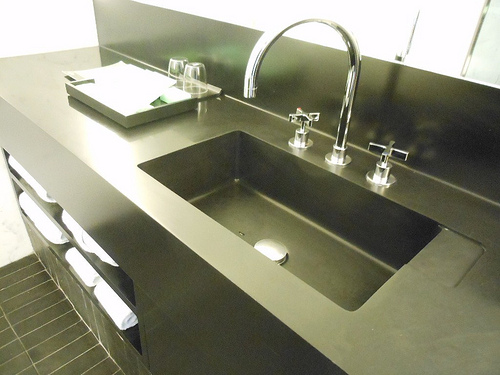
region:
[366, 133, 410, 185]
the right silver faucet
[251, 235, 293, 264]
the drain in the sink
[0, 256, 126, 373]
black floor tiles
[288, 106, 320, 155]
left silver faucet on the sink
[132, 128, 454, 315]
rectangular sink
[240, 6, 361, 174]
round spigot on the sink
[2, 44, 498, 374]
large rectangular countertop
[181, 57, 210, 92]
right clear upsidedown cup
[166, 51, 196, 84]
left clear upsidedown cup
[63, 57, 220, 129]
silver tray for accessories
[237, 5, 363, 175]
curved metal sink faucet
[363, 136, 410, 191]
silver metal sink handle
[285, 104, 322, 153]
silver metal sink handle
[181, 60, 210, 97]
clear glass cup on black counter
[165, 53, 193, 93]
clear glass cup on black counter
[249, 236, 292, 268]
silver metal drain stopper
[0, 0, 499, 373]
black sink counter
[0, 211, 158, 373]
brown tiled floor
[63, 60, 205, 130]
small rectangular tray on counter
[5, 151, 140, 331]
white folded towels on shelves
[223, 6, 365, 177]
faucet for the sink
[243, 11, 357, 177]
the faucet is silver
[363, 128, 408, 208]
handles for the sink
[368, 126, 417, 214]
the handles are silver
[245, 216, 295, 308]
drain in the sink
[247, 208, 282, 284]
the drain is silver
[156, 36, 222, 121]
cups next to the sink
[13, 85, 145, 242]
the counter is black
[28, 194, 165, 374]
towels on the shelves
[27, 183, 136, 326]
the towels are white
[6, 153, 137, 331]
Towels on a shelf.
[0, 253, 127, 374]
Tile on a floor.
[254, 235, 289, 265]
A drain in the sink.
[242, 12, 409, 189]
A faucet on a sink.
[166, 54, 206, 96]
Two upside down glasses.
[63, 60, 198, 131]
Tray and papers on a counter.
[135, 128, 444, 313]
A stainless steel sink.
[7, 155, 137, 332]
Towels under a sink.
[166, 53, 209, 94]
Two clear glasses on the counter.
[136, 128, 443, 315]
A square silver sink.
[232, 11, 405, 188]
The faucet is silver.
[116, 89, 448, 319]
The sink is rectangular.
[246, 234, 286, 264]
The drain is silver.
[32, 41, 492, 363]
The counter is black.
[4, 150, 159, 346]
The towels are white.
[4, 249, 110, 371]
The floor is black.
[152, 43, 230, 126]
The cups are clear.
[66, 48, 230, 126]
The napkins are on the table.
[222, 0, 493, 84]
The mirror is behind the sink.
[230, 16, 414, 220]
The faucet is off.